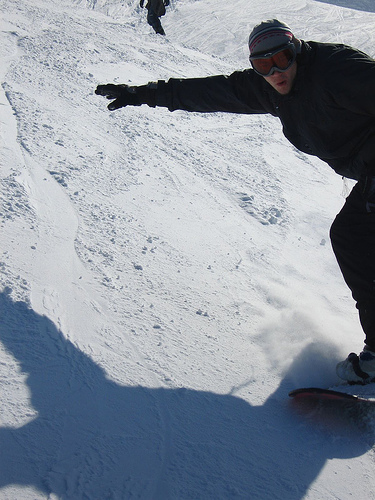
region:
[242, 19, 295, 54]
the man is wearing a hat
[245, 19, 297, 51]
the hat has stripes on it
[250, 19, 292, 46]
a stripe on the has is white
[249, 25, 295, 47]
a stripe in the hat is red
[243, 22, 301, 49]
a stripe on the hat is black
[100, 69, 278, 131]
the man's arm is extended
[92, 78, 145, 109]
the man is wearing a glove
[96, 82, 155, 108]
the glove is black in color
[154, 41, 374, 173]
the man is wearing a jacket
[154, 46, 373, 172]
the jacket is black in color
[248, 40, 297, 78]
red and gray colored goggles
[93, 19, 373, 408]
man on a snowboard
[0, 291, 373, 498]
shadow on the snow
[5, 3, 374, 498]
the ground is covered in snow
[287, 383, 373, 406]
a snow board with a black rim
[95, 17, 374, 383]
a man with black clothing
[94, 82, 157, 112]
a hand covered with a black glove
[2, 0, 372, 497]
tracks in the snow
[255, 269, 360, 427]
snow flying around the snowboarder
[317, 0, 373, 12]
a gray blue sky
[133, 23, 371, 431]
person on snow board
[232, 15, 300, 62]
person wearing grey hat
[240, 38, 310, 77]
person wearing grey goggles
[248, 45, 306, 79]
grey goggles have orange tint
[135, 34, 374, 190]
man wearing black jacket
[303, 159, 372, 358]
person wearing black pants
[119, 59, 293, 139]
person has arm extended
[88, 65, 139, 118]
person has black gloves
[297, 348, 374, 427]
snow on top of snow board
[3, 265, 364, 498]
person casting large shadow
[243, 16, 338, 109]
the head of a man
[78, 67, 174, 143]
a man wearing a glove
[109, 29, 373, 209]
a man wearing a black jacket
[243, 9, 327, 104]
a man wearing a hat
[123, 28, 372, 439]
a man riding a snowboard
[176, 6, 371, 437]
a man in lots of snow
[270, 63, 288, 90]
the nose of a man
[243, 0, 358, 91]
a man wearing ski goggles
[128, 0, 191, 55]
a person in the back ground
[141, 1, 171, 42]
a person snowboarding during the day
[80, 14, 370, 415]
a man snowboarding during the day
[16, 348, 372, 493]
shadow of a man snowboarding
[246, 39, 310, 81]
googles on a man's head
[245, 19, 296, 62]
a beanie on a man's head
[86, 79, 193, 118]
a glove on a man's hand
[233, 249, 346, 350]
snow being thrown in the air from a snowboard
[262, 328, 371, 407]
a snowboard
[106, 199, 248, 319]
white snow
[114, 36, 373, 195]
a jacket on a man's back